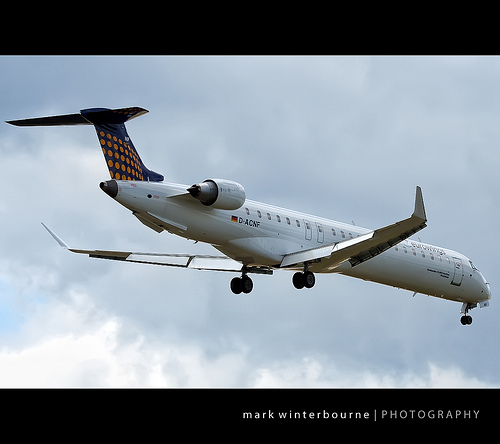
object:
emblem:
[229, 214, 261, 229]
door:
[314, 221, 324, 243]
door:
[302, 219, 312, 241]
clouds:
[268, 345, 498, 389]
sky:
[311, 55, 499, 150]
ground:
[401, 145, 431, 192]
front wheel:
[459, 314, 473, 325]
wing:
[279, 183, 427, 274]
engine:
[185, 176, 248, 212]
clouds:
[2, 264, 243, 391]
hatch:
[449, 256, 464, 287]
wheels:
[292, 270, 316, 290]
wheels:
[229, 274, 254, 296]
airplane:
[2, 105, 492, 327]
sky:
[34, 278, 399, 374]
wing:
[38, 217, 252, 273]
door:
[450, 256, 464, 287]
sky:
[173, 81, 307, 138]